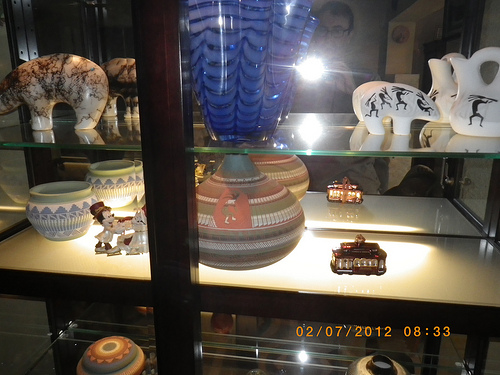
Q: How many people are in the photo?
A: None.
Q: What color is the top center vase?
A: Blue.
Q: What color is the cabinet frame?
A: Brown.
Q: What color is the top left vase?
A: White.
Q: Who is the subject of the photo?
A: The vases.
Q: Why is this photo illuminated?
A: Sunlight.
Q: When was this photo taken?
A: 02/07/2012.